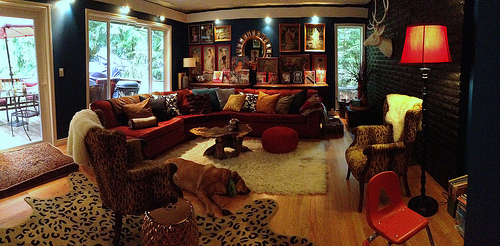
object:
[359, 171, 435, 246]
chair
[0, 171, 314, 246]
rug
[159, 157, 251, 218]
dog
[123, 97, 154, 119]
pillow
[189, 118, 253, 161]
table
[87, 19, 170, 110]
window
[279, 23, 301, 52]
picture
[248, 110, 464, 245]
floor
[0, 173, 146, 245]
carpet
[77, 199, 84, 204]
print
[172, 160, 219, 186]
fur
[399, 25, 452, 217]
lamp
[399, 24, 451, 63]
shade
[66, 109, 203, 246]
chair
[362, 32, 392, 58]
head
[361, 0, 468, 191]
wall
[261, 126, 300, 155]
ottoman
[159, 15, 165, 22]
light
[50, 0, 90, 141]
wall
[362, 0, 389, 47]
antlers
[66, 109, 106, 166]
blanket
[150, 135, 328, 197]
rug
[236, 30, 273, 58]
mirror